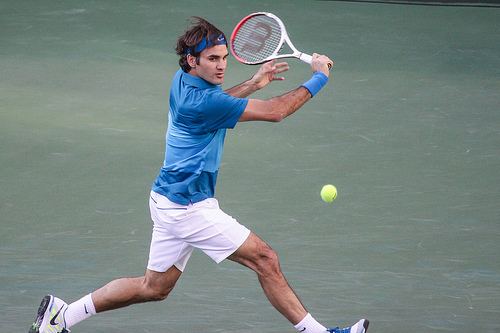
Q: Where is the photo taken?
A: Tennis court.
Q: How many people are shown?
A: 1.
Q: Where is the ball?
A: Mid-air.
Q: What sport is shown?
A: Tennis.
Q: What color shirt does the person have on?
A: Blue striped.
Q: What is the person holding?
A: Tennis racket.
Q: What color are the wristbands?
A: Blue.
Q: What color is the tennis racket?
A: White and red.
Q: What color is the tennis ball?
A: Neon green.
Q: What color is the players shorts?
A: White.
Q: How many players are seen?
A: One.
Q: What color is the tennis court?
A: Green.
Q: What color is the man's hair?
A: Brown.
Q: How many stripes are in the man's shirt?
A: Three.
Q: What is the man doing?
A: Playing tennis.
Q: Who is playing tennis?
A: A man wearing blue tennis shirt.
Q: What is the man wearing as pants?
A: White tennis shorts.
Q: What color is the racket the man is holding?
A: White and red.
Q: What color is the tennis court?
A: Green.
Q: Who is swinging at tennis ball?
A: The man.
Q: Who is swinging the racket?
A: Man wearing blue shirt.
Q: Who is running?
A: Man wearing white shorts.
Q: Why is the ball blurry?
A: It's in motion.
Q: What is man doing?
A: Playing tennis.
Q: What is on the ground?
A: Turf.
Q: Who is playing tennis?
A: Man.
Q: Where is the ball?
A: In the air.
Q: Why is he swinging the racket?
A: To hit the ball.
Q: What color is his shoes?
A: White.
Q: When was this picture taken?
A: Daytime.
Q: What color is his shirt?
A: Blue.